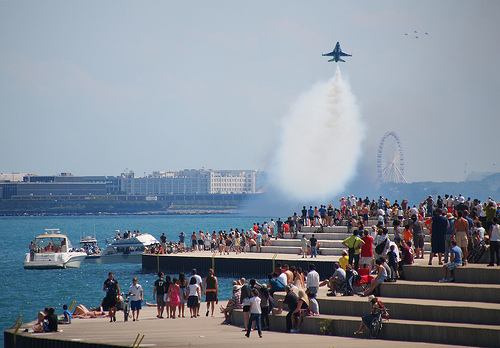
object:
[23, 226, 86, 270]
boats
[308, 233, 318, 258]
people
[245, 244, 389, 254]
stairs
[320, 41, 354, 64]
jet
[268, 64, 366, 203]
trail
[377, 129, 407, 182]
ferris wheel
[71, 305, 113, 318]
woman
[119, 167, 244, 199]
hotels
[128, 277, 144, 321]
man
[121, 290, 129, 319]
bicycle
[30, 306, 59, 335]
people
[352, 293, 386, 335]
woman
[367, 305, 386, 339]
bike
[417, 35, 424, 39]
jets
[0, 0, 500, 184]
sky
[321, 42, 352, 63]
air show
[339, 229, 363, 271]
spectators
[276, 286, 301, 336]
people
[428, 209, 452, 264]
people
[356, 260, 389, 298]
people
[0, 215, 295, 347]
water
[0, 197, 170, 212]
hillside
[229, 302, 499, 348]
stair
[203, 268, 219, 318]
people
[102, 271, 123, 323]
people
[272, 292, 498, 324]
steps